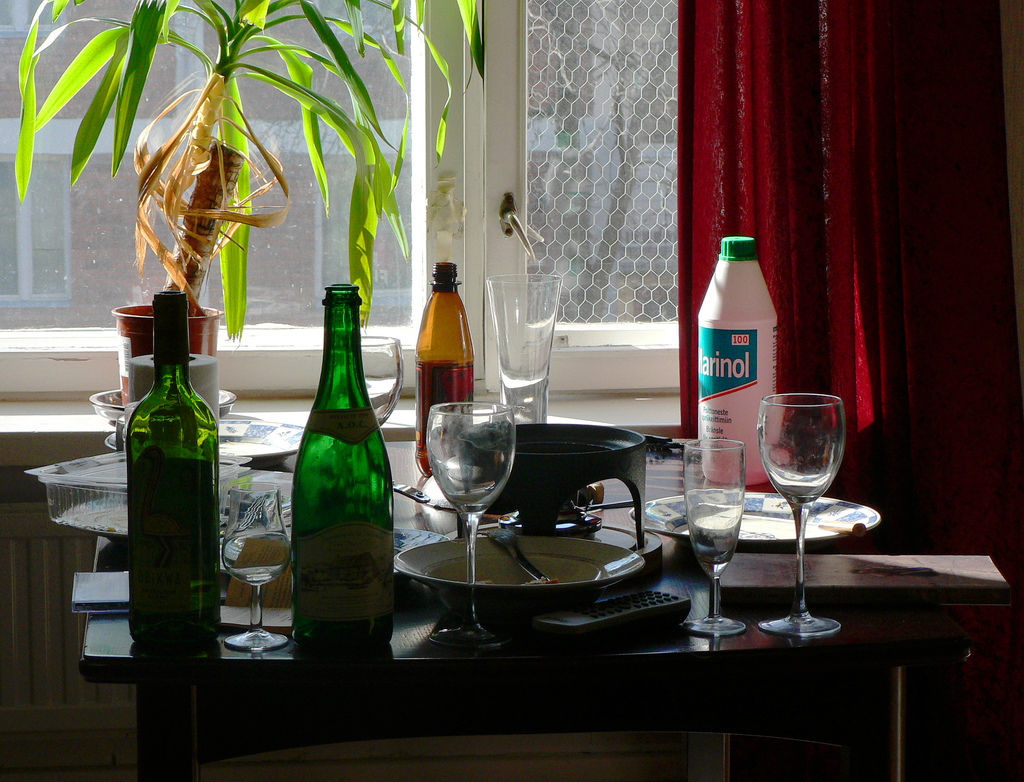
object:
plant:
[9, 2, 486, 340]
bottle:
[285, 273, 408, 702]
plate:
[628, 488, 883, 543]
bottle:
[693, 233, 781, 487]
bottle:
[406, 261, 482, 476]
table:
[0, 460, 1024, 779]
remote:
[527, 587, 691, 639]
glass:
[670, 432, 750, 640]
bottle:
[115, 283, 228, 655]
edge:
[74, 626, 992, 685]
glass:
[414, 393, 520, 659]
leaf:
[101, 0, 158, 181]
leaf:
[33, 30, 121, 138]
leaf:
[296, 0, 398, 152]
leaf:
[238, 63, 384, 331]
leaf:
[6, 4, 49, 206]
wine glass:
[751, 384, 853, 640]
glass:
[486, 263, 566, 421]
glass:
[214, 475, 302, 652]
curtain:
[674, 0, 1022, 777]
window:
[0, 0, 1023, 469]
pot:
[144, 288, 197, 365]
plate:
[391, 520, 649, 624]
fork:
[480, 520, 557, 591]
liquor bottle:
[408, 250, 482, 480]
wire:
[529, 0, 679, 324]